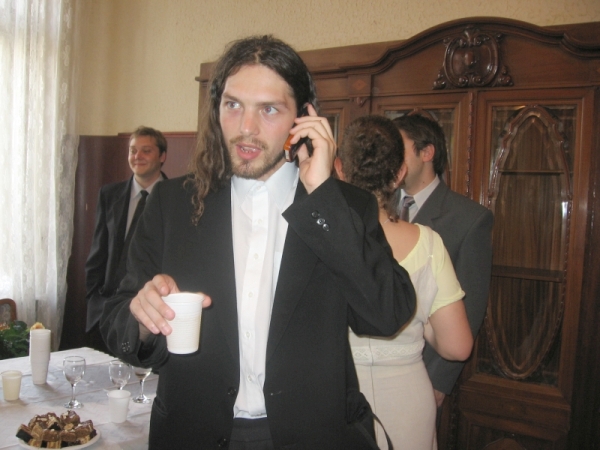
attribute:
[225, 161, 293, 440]
shirt — white, dress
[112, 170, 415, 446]
jacket — black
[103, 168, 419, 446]
blazer — black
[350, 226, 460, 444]
dress — yellow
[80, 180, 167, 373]
suit — black